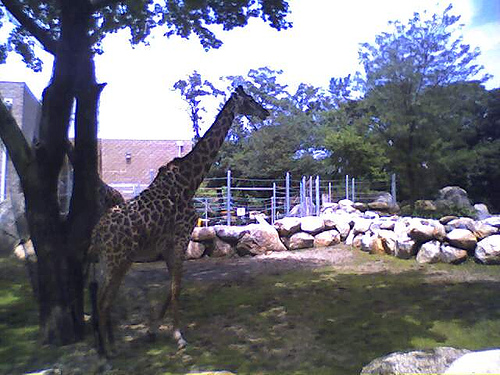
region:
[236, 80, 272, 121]
the head of a giraffe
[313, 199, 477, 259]
a fence of stones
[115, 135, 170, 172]
the roof of a house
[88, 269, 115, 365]
the hind legs of a giraffe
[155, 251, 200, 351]
the front legs of a giraffe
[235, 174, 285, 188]
a wire on the fence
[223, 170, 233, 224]
a pole on the fence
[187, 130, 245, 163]
the neck of a giraffe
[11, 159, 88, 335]
the trunk of a tree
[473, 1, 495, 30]
Small patch of blue sky.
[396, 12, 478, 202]
Green trees behind the rocks.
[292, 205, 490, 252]
Rocks line the enclosure.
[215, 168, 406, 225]
A fence behind the rocks.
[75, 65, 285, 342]
A giraffe gazing in the distance.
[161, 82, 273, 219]
The giraffe is covered with brown spots.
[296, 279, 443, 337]
Green grass for the giraffe to walk on.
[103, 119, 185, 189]
A brick building behind the fence.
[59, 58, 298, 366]
giraffe has brown and white spots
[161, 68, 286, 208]
giraffe has long neck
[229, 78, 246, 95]
small horns on giraffe's head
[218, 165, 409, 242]
fence made of metal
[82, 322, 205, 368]
giraffes hooves are light brown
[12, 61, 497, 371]
tree casting shade in pen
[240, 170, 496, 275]
large pile of rocks in sun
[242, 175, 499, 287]
sun shining on rocks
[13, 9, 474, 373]
a giraffe in the area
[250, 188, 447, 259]
stones around the giraffe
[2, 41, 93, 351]
a wooden tree trunk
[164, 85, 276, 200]
a long neck on the giraffe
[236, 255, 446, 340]
there is sparse green grass on the ground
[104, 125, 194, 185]
a red building in the area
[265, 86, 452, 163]
trees near in the environment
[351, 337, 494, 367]
an object on the bottom of the picture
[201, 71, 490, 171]
the giraffe is looking at something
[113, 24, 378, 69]
the sky is hazy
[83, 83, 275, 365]
a giraffe standing next to a tree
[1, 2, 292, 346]
a large tree next to the giraffe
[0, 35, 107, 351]
the intertwining trunk of the tree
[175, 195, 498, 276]
rocks placed on the periphery of the enclosure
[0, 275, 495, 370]
a grassy area of the ground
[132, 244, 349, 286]
a patch of dirt near the rocks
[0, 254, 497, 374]
the shadow of the tree on the ground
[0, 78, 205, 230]
a large brick building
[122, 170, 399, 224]
a fence behind the pile of rocks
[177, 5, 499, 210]
a bunch of trees behind the enclosure